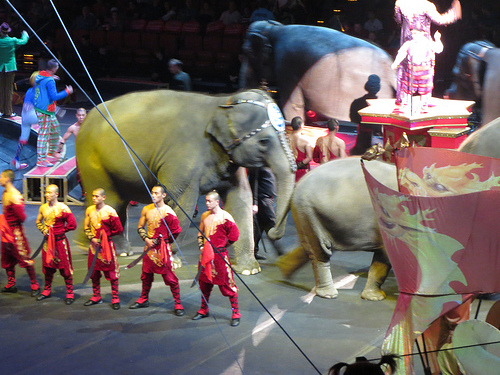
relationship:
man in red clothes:
[192, 190, 240, 326] [196, 211, 241, 321]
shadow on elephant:
[243, 21, 375, 119] [243, 21, 400, 134]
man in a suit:
[169, 57, 193, 91] [171, 70, 193, 91]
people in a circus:
[1, 21, 241, 326] [1, 0, 499, 373]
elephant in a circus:
[76, 86, 300, 277] [1, 0, 499, 373]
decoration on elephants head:
[225, 89, 298, 174] [232, 89, 288, 170]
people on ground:
[1, 169, 242, 329] [1, 82, 499, 373]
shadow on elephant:
[243, 21, 375, 119] [76, 86, 300, 277]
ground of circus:
[1, 82, 499, 373] [1, 0, 499, 373]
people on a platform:
[391, 1, 462, 119] [361, 92, 477, 147]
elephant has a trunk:
[76, 86, 300, 277] [267, 141, 297, 241]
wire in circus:
[8, 0, 325, 374] [1, 0, 499, 373]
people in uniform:
[1, 169, 242, 329] [1, 190, 244, 319]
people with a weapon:
[1, 169, 242, 329] [28, 229, 50, 260]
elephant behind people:
[76, 86, 300, 277] [1, 169, 242, 329]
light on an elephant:
[285, 48, 397, 124] [243, 21, 400, 134]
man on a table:
[34, 58, 73, 167] [1, 114, 80, 204]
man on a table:
[1, 24, 32, 119] [1, 114, 80, 204]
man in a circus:
[192, 190, 240, 326] [1, 0, 499, 373]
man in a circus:
[58, 106, 87, 150] [1, 0, 499, 373]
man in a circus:
[1, 24, 32, 119] [1, 0, 499, 373]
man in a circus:
[34, 58, 73, 167] [1, 0, 499, 373]